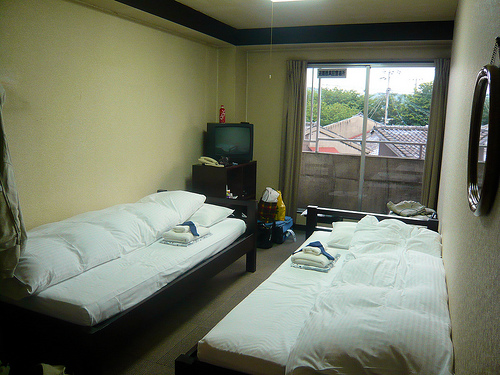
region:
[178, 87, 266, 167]
black tv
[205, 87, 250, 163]
black tv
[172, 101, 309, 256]
black tv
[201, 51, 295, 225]
black tv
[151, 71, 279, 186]
black tv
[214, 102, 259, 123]
RED BOTTLE ON TOP OF TV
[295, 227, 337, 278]
TOWELS ARE FOLDING ON THE BED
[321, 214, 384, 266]
ONE PILLOW ON EACH BED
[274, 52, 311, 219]
CURTAINS ARE DRAWN TO THE LEFT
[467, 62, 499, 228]
MIRROR IS ON RIGHT WALL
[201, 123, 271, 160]
TELEVISION IS BLACK IN COLOR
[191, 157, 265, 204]
TELEVISION IS ON TOP OF STAND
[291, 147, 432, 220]
WALL IN BACKGROUND IS TAN IN COLOR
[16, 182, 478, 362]
ROOM HAS TOTAL OF TWO BEDS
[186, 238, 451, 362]
SHEETS ON BED ARE WHITE IN COLOR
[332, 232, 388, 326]
the bed is white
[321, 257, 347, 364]
the bed is white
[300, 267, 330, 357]
the bed is white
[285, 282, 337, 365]
the bed is white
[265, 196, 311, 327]
the bed is white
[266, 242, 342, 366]
the bed is white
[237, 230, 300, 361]
the bed is white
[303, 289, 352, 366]
the pillows are white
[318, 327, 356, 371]
the pillows are white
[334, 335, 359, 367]
the pillows are white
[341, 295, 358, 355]
the pillows are white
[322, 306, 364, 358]
the pillows are white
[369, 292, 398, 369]
the pillows are white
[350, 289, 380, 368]
the pillows are white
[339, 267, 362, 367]
the pillows are white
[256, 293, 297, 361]
the bed is white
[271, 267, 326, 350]
the bed is white